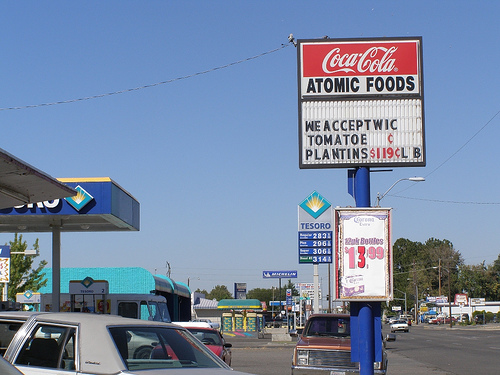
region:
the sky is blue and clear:
[27, 15, 149, 68]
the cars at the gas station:
[15, 302, 352, 373]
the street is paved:
[411, 330, 498, 370]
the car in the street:
[386, 311, 421, 330]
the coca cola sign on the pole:
[289, 33, 437, 178]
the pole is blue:
[341, 167, 388, 371]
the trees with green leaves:
[395, 240, 498, 296]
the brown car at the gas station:
[289, 312, 378, 374]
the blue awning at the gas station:
[1, 173, 141, 232]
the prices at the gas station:
[295, 189, 341, 269]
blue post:
[350, 317, 380, 354]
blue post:
[327, 310, 397, 351]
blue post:
[317, 294, 379, 369]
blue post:
[344, 311, 391, 372]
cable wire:
[88, 55, 215, 147]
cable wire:
[81, 17, 196, 184]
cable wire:
[101, 34, 245, 226]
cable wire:
[144, 50, 224, 108]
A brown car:
[286, 310, 393, 373]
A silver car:
[6, 301, 268, 373]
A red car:
[158, 317, 236, 368]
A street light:
[368, 169, 431, 216]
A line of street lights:
[394, 267, 470, 328]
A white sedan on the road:
[388, 314, 409, 336]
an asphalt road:
[376, 318, 498, 372]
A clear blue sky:
[5, 1, 499, 278]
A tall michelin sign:
[259, 261, 303, 309]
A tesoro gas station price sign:
[285, 189, 340, 272]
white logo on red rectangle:
[299, 36, 425, 79]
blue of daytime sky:
[72, 11, 208, 65]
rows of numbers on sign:
[306, 226, 332, 267]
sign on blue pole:
[328, 186, 401, 344]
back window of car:
[92, 312, 222, 372]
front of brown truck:
[292, 312, 358, 367]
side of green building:
[110, 266, 148, 291]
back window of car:
[13, 318, 83, 370]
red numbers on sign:
[368, 142, 402, 164]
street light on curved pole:
[390, 169, 431, 193]